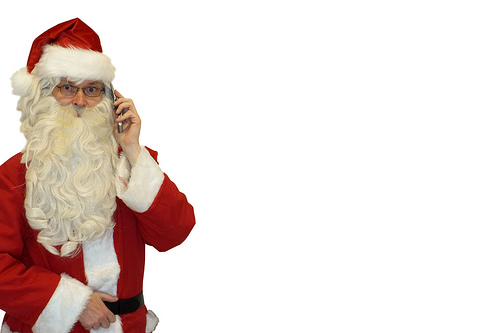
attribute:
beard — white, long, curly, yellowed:
[17, 82, 119, 256]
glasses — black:
[53, 79, 104, 101]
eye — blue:
[62, 83, 74, 93]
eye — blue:
[85, 84, 97, 94]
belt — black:
[107, 290, 146, 318]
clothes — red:
[2, 14, 193, 330]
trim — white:
[28, 46, 118, 80]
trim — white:
[109, 146, 163, 214]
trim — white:
[30, 271, 90, 332]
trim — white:
[78, 240, 125, 331]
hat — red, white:
[12, 18, 116, 95]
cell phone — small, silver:
[111, 89, 124, 132]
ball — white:
[7, 69, 33, 99]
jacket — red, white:
[0, 146, 196, 331]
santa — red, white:
[3, 15, 196, 323]